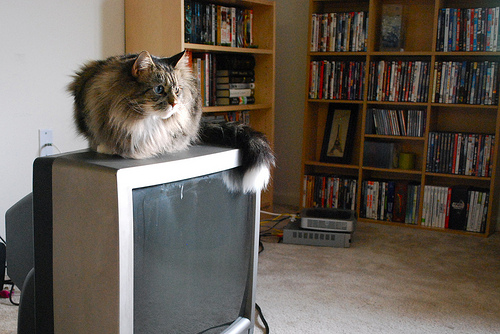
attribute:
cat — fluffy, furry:
[67, 42, 222, 158]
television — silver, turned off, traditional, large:
[26, 143, 262, 333]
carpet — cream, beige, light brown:
[264, 246, 495, 334]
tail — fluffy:
[199, 106, 277, 195]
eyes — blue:
[153, 82, 181, 96]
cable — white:
[261, 207, 299, 222]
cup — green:
[395, 151, 415, 169]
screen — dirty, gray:
[130, 164, 253, 334]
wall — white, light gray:
[2, 4, 126, 55]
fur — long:
[70, 46, 275, 191]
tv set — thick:
[3, 128, 262, 332]